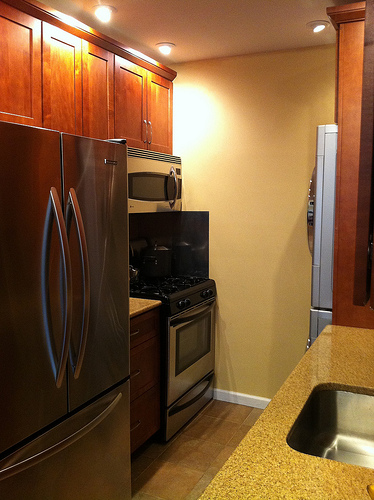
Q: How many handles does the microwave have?
A: One.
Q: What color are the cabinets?
A: Brown.